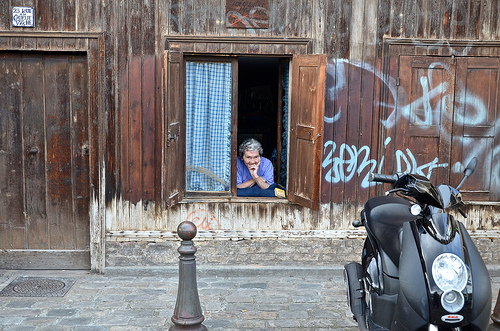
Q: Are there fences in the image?
A: No, there are no fences.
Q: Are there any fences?
A: No, there are no fences.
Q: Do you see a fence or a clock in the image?
A: No, there are no fences or clocks.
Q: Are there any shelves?
A: No, there are no shelves.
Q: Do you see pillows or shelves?
A: No, there are no shelves or pillows.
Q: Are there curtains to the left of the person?
A: Yes, there is a curtain to the left of the person.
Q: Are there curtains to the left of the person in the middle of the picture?
A: Yes, there is a curtain to the left of the person.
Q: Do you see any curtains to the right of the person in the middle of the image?
A: No, the curtain is to the left of the person.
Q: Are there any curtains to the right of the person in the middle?
A: No, the curtain is to the left of the person.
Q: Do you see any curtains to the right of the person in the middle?
A: No, the curtain is to the left of the person.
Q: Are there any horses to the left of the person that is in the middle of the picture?
A: No, there is a curtain to the left of the person.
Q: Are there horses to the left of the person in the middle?
A: No, there is a curtain to the left of the person.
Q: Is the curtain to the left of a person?
A: Yes, the curtain is to the left of a person.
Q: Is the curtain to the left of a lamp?
A: No, the curtain is to the left of a person.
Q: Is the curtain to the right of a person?
A: No, the curtain is to the left of a person.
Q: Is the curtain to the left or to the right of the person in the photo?
A: The curtain is to the left of the person.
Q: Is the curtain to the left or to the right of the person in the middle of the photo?
A: The curtain is to the left of the person.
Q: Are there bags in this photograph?
A: No, there are no bags.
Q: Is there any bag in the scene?
A: No, there are no bags.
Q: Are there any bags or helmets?
A: No, there are no bags or helmets.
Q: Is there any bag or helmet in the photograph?
A: No, there are no bags or helmets.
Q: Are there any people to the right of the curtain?
A: Yes, there is a person to the right of the curtain.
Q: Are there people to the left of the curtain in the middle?
A: No, the person is to the right of the curtain.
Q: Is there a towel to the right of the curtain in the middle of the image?
A: No, there is a person to the right of the curtain.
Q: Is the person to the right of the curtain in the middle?
A: Yes, the person is to the right of the curtain.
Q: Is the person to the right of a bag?
A: No, the person is to the right of the curtain.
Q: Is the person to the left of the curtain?
A: No, the person is to the right of the curtain.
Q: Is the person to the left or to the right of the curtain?
A: The person is to the right of the curtain.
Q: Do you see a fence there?
A: No, there are no fences.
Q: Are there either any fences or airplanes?
A: No, there are no fences or airplanes.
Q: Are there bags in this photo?
A: No, there are no bags.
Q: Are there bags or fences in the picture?
A: No, there are no bags or fences.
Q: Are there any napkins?
A: No, there are no napkins.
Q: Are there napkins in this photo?
A: No, there are no napkins.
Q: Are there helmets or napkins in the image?
A: No, there are no napkins or helmets.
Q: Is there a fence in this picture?
A: No, there are no fences.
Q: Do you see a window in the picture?
A: Yes, there is a window.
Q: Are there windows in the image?
A: Yes, there is a window.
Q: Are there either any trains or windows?
A: Yes, there is a window.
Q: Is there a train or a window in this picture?
A: Yes, there is a window.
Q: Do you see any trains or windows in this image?
A: Yes, there is a window.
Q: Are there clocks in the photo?
A: No, there are no clocks.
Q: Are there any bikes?
A: Yes, there is a bike.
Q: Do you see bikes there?
A: Yes, there is a bike.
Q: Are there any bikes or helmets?
A: Yes, there is a bike.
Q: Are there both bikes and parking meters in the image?
A: No, there is a bike but no parking meters.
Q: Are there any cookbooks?
A: No, there are no cookbooks.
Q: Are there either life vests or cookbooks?
A: No, there are no cookbooks or life vests.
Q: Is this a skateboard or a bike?
A: This is a bike.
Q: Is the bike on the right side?
A: Yes, the bike is on the right of the image.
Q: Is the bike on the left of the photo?
A: No, the bike is on the right of the image.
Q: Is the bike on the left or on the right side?
A: The bike is on the right of the image.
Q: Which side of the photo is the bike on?
A: The bike is on the right of the image.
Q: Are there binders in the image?
A: No, there are no binders.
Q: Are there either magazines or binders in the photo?
A: No, there are no binders or magazines.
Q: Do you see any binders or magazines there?
A: No, there are no binders or magazines.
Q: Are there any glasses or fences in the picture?
A: No, there are no fences or glasses.